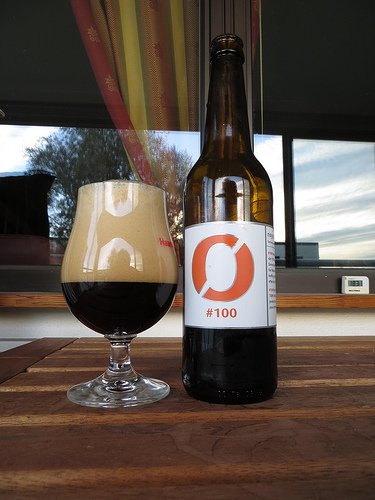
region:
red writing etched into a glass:
[154, 232, 175, 249]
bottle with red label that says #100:
[199, 306, 238, 318]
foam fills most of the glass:
[64, 161, 184, 295]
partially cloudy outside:
[301, 147, 370, 228]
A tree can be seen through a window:
[24, 125, 191, 185]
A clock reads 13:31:
[333, 270, 371, 297]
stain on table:
[156, 418, 348, 498]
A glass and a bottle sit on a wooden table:
[50, 28, 329, 451]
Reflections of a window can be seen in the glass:
[71, 174, 162, 281]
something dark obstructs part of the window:
[0, 161, 65, 267]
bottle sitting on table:
[178, 26, 286, 416]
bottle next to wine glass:
[167, 25, 282, 412]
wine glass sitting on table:
[53, 180, 184, 414]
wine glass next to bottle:
[57, 179, 185, 410]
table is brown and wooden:
[3, 331, 373, 497]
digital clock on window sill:
[338, 272, 372, 296]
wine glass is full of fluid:
[57, 178, 182, 341]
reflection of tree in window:
[21, 124, 204, 261]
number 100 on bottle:
[213, 304, 238, 321]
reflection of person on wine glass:
[102, 245, 143, 290]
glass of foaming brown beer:
[59, 178, 179, 411]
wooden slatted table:
[2, 328, 374, 497]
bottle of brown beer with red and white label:
[177, 28, 284, 409]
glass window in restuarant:
[2, 2, 374, 299]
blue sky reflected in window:
[1, 129, 373, 265]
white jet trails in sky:
[250, 136, 373, 257]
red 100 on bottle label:
[205, 304, 238, 322]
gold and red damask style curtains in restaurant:
[72, 0, 261, 229]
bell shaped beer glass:
[57, 174, 178, 415]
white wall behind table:
[1, 309, 372, 354]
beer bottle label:
[184, 220, 275, 329]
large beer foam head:
[59, 180, 178, 283]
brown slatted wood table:
[0, 336, 373, 498]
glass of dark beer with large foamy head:
[60, 179, 177, 408]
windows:
[0, 125, 374, 267]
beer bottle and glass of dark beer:
[60, 31, 277, 410]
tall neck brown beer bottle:
[180, 35, 279, 403]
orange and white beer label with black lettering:
[181, 222, 278, 327]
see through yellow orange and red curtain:
[66, 2, 258, 184]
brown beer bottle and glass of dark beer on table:
[0, 35, 373, 497]